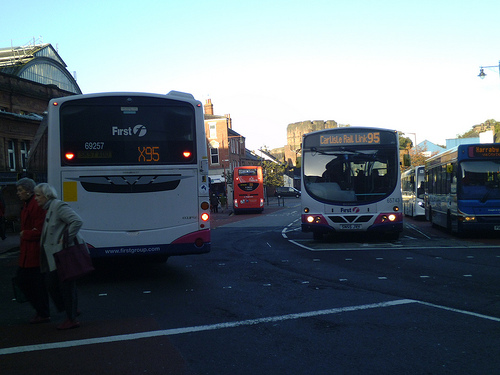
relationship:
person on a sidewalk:
[207, 190, 222, 211] [203, 190, 253, 226]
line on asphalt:
[0, 298, 498, 357] [0, 198, 498, 373]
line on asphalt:
[281, 215, 499, 252] [0, 198, 498, 373]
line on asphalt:
[401, 218, 431, 242] [0, 198, 498, 373]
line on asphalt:
[376, 274, 387, 281] [0, 198, 498, 373]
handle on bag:
[56, 220, 85, 251] [52, 227, 98, 278]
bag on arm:
[52, 227, 98, 278] [59, 205, 81, 243]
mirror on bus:
[401, 147, 412, 169] [301, 126, 404, 240]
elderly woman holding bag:
[34, 183, 83, 330] [48, 230, 107, 304]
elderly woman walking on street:
[34, 183, 83, 330] [22, 202, 497, 371]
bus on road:
[302, 124, 404, 238] [18, 236, 486, 354]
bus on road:
[425, 143, 500, 234] [18, 236, 486, 354]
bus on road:
[29, 91, 207, 260] [18, 236, 486, 354]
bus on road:
[231, 165, 264, 213] [18, 236, 486, 354]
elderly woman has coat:
[15, 176, 49, 322] [16, 194, 43, 259]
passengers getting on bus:
[208, 190, 228, 215] [229, 162, 264, 213]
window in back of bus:
[63, 102, 198, 159] [29, 91, 207, 260]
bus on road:
[302, 124, 404, 238] [115, 267, 492, 370]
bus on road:
[29, 91, 207, 260] [115, 267, 492, 370]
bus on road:
[425, 143, 500, 234] [115, 267, 492, 370]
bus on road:
[401, 165, 426, 215] [115, 267, 492, 370]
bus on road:
[231, 165, 264, 213] [115, 267, 492, 370]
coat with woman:
[40, 197, 85, 272] [33, 182, 94, 282]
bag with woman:
[51, 227, 93, 273] [33, 182, 94, 282]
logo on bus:
[110, 123, 150, 143] [26, 76, 220, 271]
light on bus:
[60, 150, 77, 161] [14, 81, 217, 278]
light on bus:
[180, 149, 196, 159] [14, 81, 217, 278]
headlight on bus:
[464, 216, 474, 220] [302, 124, 404, 238]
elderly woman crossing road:
[34, 183, 83, 330] [120, 277, 482, 372]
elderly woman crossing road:
[15, 176, 49, 322] [120, 277, 482, 372]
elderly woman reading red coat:
[15, 176, 49, 322] [12, 205, 37, 268]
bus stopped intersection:
[301, 126, 404, 240] [213, 254, 465, 328]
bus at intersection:
[425, 143, 500, 234] [193, 256, 473, 328]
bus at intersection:
[301, 126, 404, 240] [193, 256, 473, 328]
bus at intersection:
[29, 91, 207, 260] [193, 256, 473, 328]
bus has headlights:
[302, 124, 404, 238] [298, 205, 323, 225]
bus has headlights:
[302, 124, 404, 238] [378, 206, 399, 225]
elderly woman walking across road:
[1, 175, 45, 324] [183, 264, 436, 344]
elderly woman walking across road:
[32, 184, 89, 317] [183, 264, 436, 344]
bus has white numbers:
[29, 91, 207, 260] [82, 137, 104, 154]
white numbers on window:
[82, 137, 104, 154] [61, 95, 196, 165]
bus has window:
[29, 91, 207, 260] [61, 95, 196, 165]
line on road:
[0, 298, 497, 355] [179, 250, 462, 330]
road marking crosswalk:
[179, 250, 462, 330] [84, 297, 476, 368]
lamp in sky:
[477, 68, 487, 79] [1, 0, 498, 147]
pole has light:
[493, 62, 496, 130] [475, 70, 485, 76]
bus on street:
[233, 165, 265, 213] [218, 210, 280, 309]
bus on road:
[427, 141, 484, 231] [250, 247, 478, 295]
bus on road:
[302, 124, 404, 238] [250, 247, 478, 295]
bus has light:
[26, 76, 220, 271] [182, 148, 193, 157]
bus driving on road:
[301, 126, 404, 240] [215, 213, 496, 366]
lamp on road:
[473, 64, 490, 86] [6, 181, 498, 372]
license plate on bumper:
[332, 216, 377, 234] [308, 227, 400, 242]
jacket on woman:
[20, 204, 40, 268] [12, 168, 39, 218]